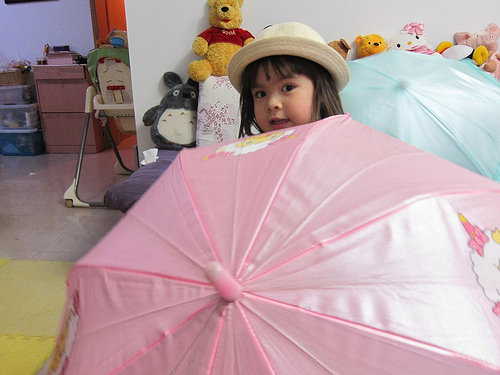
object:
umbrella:
[47, 112, 500, 375]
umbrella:
[339, 47, 499, 181]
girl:
[223, 19, 354, 138]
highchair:
[60, 28, 140, 208]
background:
[0, 0, 500, 373]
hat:
[225, 19, 351, 93]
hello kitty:
[387, 19, 441, 58]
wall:
[123, 1, 500, 157]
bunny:
[140, 68, 201, 153]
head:
[204, 0, 247, 28]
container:
[1, 128, 45, 155]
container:
[1, 104, 38, 129]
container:
[0, 84, 34, 104]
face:
[246, 60, 319, 134]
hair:
[235, 54, 343, 140]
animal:
[450, 18, 500, 74]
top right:
[410, 0, 498, 111]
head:
[230, 21, 344, 139]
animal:
[140, 68, 201, 153]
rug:
[0, 257, 75, 367]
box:
[0, 60, 31, 84]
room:
[0, 0, 499, 374]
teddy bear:
[184, 0, 259, 83]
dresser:
[31, 64, 101, 156]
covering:
[102, 149, 178, 212]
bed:
[101, 139, 188, 213]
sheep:
[204, 127, 299, 159]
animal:
[185, 0, 259, 83]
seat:
[84, 45, 135, 112]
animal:
[382, 21, 436, 56]